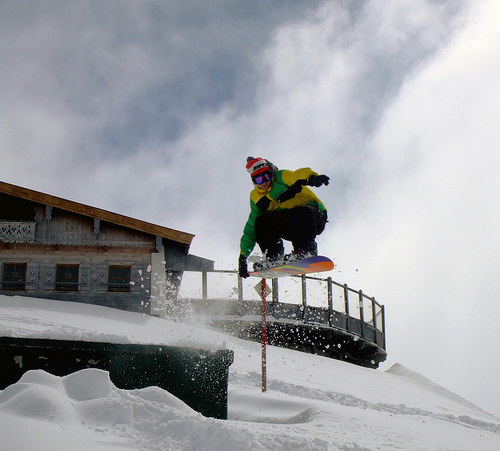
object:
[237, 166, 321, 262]
coat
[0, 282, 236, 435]
ski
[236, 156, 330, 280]
person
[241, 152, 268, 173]
beanie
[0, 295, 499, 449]
snow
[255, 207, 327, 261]
pants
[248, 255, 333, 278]
board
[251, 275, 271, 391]
sign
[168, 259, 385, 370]
patio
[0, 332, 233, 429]
jump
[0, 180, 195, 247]
roof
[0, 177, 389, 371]
building